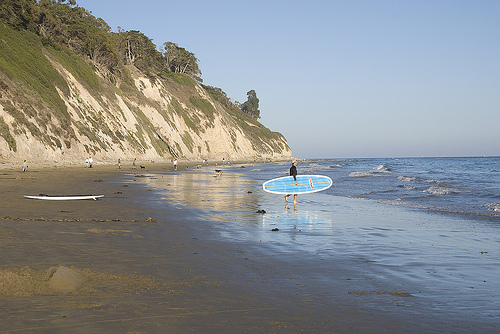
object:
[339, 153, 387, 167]
wave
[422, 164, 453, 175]
wave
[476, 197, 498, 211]
wave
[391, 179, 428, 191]
wave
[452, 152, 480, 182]
wave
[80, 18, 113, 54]
tree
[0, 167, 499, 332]
beach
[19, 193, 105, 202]
surfboard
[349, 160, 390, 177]
wave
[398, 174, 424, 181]
wave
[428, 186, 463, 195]
wave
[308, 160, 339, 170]
wave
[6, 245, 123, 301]
sand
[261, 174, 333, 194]
surfboard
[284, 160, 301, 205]
man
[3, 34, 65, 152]
grass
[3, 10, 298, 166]
cliff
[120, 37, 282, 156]
grass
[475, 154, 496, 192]
waves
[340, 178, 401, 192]
waves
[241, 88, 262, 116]
tree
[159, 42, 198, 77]
tree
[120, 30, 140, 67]
tree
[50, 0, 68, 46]
tree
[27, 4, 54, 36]
tree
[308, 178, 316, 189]
symbol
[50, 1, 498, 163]
sky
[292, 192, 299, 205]
leg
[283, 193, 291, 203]
leg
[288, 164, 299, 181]
wetsuit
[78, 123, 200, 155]
rocks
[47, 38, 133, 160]
slope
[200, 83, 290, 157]
slope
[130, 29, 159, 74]
tree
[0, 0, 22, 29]
tree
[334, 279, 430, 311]
seaweed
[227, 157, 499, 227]
ocean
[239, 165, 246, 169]
person